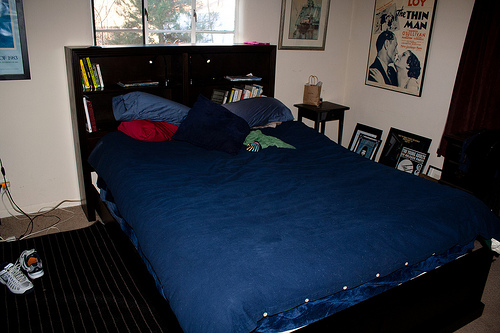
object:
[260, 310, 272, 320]
stud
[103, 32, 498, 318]
bed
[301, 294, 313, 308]
stud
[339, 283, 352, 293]
stud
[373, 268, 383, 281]
stud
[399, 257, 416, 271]
stud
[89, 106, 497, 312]
spread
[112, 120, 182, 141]
pillow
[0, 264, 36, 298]
sneaker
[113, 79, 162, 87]
books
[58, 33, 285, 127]
bed head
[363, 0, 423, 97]
poster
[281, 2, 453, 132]
wall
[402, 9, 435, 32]
movie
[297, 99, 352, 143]
table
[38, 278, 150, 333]
floor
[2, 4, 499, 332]
bedroom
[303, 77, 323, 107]
bag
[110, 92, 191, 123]
pillow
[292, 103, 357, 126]
corner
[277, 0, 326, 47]
picture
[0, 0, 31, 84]
pictures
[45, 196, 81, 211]
cords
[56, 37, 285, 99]
headboard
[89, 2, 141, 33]
window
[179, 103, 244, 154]
pillows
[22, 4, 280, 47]
wall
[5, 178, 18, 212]
wire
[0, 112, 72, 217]
wall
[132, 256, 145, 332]
line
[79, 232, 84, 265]
line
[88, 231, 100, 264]
line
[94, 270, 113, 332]
line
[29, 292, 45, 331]
line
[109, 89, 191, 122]
pillow case